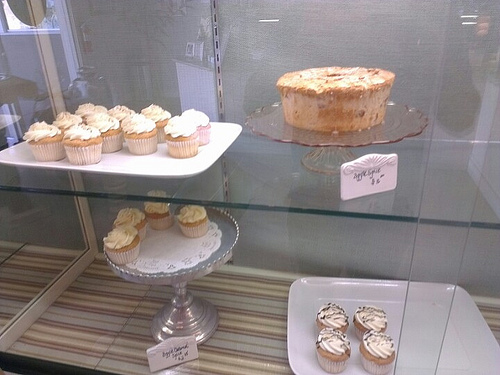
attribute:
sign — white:
[335, 157, 401, 200]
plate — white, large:
[106, 154, 194, 179]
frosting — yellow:
[67, 128, 100, 141]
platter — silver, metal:
[132, 232, 241, 274]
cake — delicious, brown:
[286, 74, 381, 130]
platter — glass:
[264, 132, 418, 150]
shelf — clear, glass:
[240, 157, 310, 200]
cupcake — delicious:
[30, 127, 57, 157]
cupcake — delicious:
[100, 120, 123, 149]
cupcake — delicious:
[108, 234, 136, 258]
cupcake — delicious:
[124, 212, 142, 231]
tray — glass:
[396, 293, 477, 369]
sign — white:
[145, 346, 209, 369]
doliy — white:
[145, 234, 198, 265]